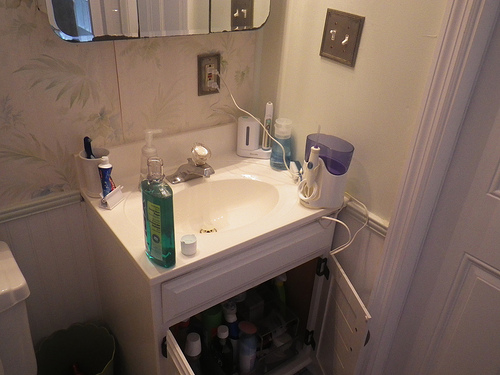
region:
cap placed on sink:
[173, 229, 208, 257]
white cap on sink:
[173, 230, 207, 263]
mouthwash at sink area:
[128, 155, 184, 279]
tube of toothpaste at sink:
[92, 153, 125, 200]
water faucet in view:
[174, 134, 215, 195]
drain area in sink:
[189, 211, 224, 235]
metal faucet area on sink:
[171, 150, 232, 193]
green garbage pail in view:
[23, 311, 121, 370]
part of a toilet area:
[1, 232, 38, 369]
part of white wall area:
[348, 110, 410, 152]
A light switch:
[317, 8, 365, 68]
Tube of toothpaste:
[95, 155, 117, 197]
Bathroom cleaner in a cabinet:
[235, 321, 255, 373]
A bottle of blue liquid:
[272, 117, 292, 172]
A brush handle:
[81, 136, 96, 158]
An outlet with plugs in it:
[199, 53, 221, 93]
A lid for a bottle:
[180, 232, 197, 257]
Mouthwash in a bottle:
[139, 155, 175, 266]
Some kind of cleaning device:
[301, 135, 353, 213]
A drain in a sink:
[200, 223, 216, 234]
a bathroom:
[2, 5, 499, 367]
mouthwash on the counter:
[143, 157, 174, 264]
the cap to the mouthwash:
[183, 237, 196, 252]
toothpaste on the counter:
[100, 157, 122, 201]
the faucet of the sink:
[180, 143, 221, 179]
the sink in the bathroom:
[181, 184, 272, 227]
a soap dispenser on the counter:
[144, 129, 157, 155]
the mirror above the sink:
[53, 5, 258, 32]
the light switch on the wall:
[316, 10, 359, 63]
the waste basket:
[41, 319, 121, 365]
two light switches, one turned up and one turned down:
[318, 6, 366, 69]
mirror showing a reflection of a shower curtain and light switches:
[43, 2, 273, 44]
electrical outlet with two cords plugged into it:
[196, 51, 222, 98]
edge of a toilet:
[0, 239, 40, 374]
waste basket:
[33, 319, 118, 374]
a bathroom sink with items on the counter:
[72, 120, 347, 288]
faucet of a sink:
[164, 140, 215, 185]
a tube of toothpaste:
[96, 154, 126, 211]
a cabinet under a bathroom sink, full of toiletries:
[159, 212, 374, 374]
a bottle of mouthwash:
[138, 154, 177, 270]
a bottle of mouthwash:
[135, 141, 187, 276]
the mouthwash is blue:
[127, 145, 193, 267]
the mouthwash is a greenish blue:
[122, 134, 180, 274]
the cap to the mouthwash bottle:
[177, 220, 195, 259]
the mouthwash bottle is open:
[134, 144, 196, 269]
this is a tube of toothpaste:
[91, 138, 126, 215]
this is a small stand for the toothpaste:
[88, 183, 149, 213]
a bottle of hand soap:
[121, 118, 178, 188]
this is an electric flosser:
[300, 102, 327, 202]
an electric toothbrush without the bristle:
[250, 80, 270, 161]